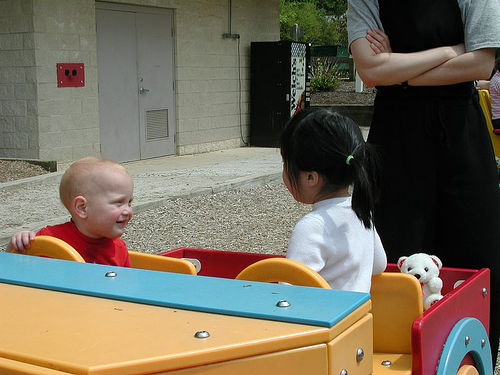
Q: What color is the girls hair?
A: Black.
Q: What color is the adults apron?
A: Black.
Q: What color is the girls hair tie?
A: Green.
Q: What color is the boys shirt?
A: Red.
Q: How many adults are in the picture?
A: One.